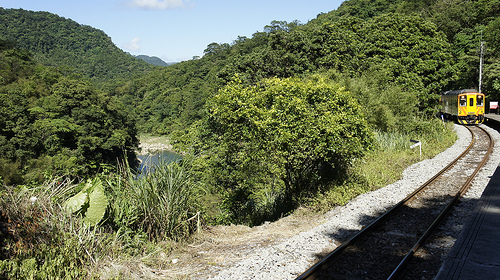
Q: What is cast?
A: Shadow.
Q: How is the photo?
A: Clear.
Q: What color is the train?
A: Yellow.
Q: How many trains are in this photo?
A: One.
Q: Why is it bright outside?
A: It's daytime.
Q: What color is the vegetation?
A: Green.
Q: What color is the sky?
A: Blue.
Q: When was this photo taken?
A: Outside, near water.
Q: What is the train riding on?
A: Train tracks.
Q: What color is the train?
A: Yellow.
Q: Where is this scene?
A: Train tracks.